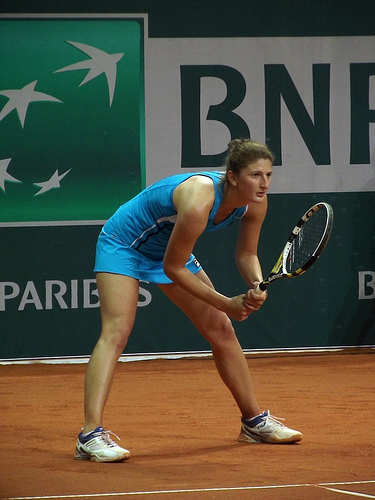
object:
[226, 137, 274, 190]
hair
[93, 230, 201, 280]
blue skirt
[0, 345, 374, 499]
tennis court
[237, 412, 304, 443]
shoe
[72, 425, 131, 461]
shoe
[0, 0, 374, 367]
wall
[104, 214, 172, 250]
tag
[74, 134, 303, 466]
player